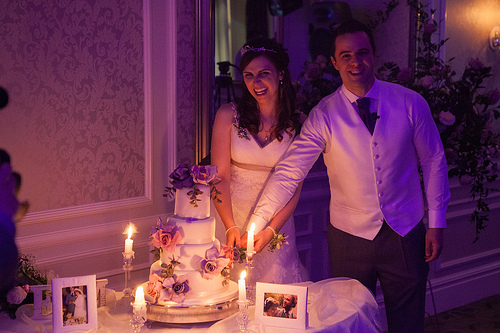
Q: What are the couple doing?
A: Cutting a cake.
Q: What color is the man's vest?
A: White.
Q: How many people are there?
A: Two.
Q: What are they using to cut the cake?
A: A knife.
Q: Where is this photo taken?
A: At a wedding reception.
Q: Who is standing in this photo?
A: A man and woman.